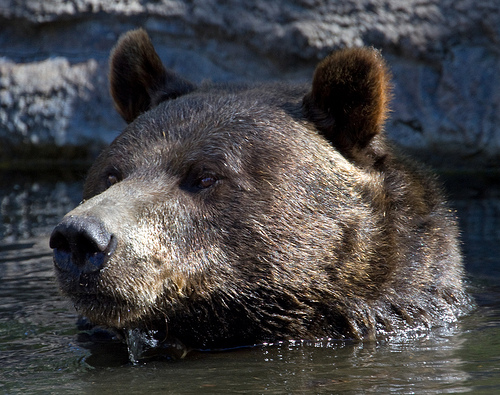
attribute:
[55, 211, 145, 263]
nose —  Black ,  brown, a grizzly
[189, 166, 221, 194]
eye —  open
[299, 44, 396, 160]
ear — the Left 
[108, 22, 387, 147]
ear — brown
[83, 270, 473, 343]
fur — wet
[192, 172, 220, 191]
eye —  two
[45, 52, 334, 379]
bear —  a grizzly ,  brown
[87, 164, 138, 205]
right eye —  the  right,  bear's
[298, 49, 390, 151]
ear — brown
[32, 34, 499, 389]
bear —  bear's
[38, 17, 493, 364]
head —  brown,  bear's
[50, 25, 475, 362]
bear's head —  bear's,  brown,  a grizzly's 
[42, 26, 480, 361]
bear —  brown, a grizzle,  alert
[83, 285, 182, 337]
mouth — closed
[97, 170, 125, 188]
eye —  the left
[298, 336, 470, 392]
reflection —  bear's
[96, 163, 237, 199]
eyes — brown